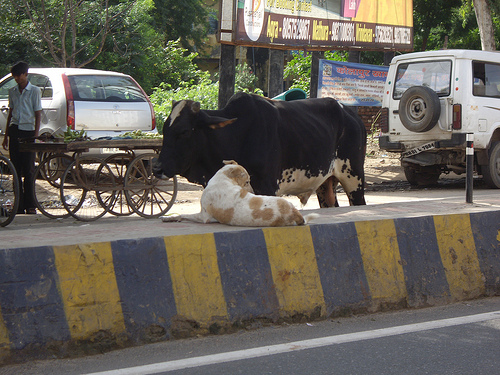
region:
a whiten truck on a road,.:
[378, 38, 497, 192]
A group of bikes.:
[1, 117, 185, 222]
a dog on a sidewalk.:
[191, 146, 311, 235]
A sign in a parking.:
[216, 5, 418, 67]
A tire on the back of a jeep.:
[392, 76, 438, 131]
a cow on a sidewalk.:
[155, 85, 395, 208]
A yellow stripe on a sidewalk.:
[48, 241, 135, 348]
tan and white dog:
[154, 157, 319, 248]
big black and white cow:
[151, 80, 371, 212]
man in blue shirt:
[3, 54, 41, 218]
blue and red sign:
[315, 51, 397, 111]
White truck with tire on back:
[381, 48, 498, 200]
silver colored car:
[1, 53, 161, 175]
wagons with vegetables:
[41, 123, 165, 222]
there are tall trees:
[13, 3, 194, 95]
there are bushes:
[150, 75, 220, 107]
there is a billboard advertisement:
[221, 0, 421, 47]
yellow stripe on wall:
[46, 251, 141, 346]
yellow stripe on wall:
[155, 236, 234, 343]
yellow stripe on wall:
[263, 227, 339, 321]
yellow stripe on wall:
[358, 221, 435, 308]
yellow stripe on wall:
[436, 207, 496, 313]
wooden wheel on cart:
[128, 147, 180, 215]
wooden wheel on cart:
[95, 149, 151, 211]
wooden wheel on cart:
[61, 157, 126, 227]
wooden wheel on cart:
[31, 157, 86, 222]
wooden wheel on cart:
[5, 157, 26, 221]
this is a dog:
[173, 164, 333, 257]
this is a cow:
[147, 95, 377, 217]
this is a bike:
[30, 121, 178, 228]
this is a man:
[2, 56, 72, 218]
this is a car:
[0, 44, 161, 161]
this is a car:
[383, 46, 495, 194]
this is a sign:
[226, 1, 412, 57]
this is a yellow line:
[159, 236, 228, 336]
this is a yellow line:
[254, 215, 329, 332]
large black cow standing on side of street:
[148, 83, 374, 210]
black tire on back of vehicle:
[396, 83, 443, 134]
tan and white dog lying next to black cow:
[146, 155, 313, 225]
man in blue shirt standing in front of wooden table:
[0, 57, 50, 212]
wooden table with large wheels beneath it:
[14, 125, 181, 223]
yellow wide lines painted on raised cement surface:
[38, 205, 499, 343]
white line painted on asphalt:
[88, 308, 499, 374]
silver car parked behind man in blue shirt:
[0, 57, 163, 173]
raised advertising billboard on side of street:
[213, 0, 418, 121]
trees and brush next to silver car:
[1, 0, 224, 132]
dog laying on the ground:
[159, 158, 306, 227]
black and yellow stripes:
[0, 211, 498, 353]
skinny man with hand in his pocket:
[1, 58, 45, 219]